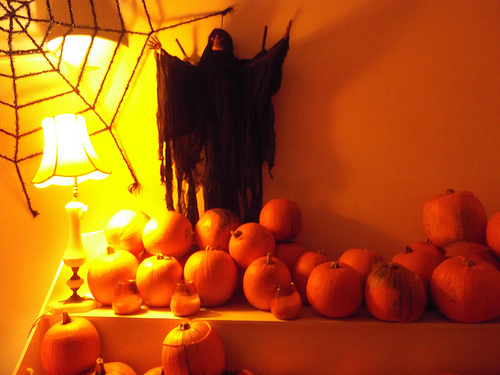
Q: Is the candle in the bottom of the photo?
A: Yes, the candle is in the bottom of the image.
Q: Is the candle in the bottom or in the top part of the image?
A: The candle is in the bottom of the image.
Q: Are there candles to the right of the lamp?
A: Yes, there is a candle to the right of the lamp.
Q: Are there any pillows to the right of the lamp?
A: No, there is a candle to the right of the lamp.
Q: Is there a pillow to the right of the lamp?
A: No, there is a candle to the right of the lamp.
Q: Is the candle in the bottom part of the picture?
A: Yes, the candle is in the bottom of the image.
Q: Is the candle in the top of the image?
A: No, the candle is in the bottom of the image.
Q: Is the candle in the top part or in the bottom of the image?
A: The candle is in the bottom of the image.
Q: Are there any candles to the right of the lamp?
A: Yes, there is a candle to the right of the lamp.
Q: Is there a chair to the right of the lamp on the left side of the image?
A: No, there is a candle to the right of the lamp.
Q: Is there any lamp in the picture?
A: Yes, there is a lamp.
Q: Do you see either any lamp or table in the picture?
A: Yes, there is a lamp.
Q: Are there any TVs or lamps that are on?
A: Yes, the lamp is on.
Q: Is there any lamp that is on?
A: Yes, there is a lamp that is on.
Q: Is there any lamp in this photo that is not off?
A: Yes, there is a lamp that is on.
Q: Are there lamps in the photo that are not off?
A: Yes, there is a lamp that is on.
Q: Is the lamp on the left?
A: Yes, the lamp is on the left of the image.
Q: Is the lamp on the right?
A: No, the lamp is on the left of the image.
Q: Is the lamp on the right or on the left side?
A: The lamp is on the left of the image.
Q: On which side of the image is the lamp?
A: The lamp is on the left of the image.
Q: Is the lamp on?
A: Yes, the lamp is on.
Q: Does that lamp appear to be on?
A: Yes, the lamp is on.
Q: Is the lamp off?
A: No, the lamp is on.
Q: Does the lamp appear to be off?
A: No, the lamp is on.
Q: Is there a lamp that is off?
A: No, there is a lamp but it is on.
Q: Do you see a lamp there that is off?
A: No, there is a lamp but it is on.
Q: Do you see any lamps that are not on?
A: No, there is a lamp but it is on.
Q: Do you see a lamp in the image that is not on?
A: No, there is a lamp but it is on.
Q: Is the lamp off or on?
A: The lamp is on.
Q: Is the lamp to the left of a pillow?
A: No, the lamp is to the left of a pumpkin.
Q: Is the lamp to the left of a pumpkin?
A: Yes, the lamp is to the left of a pumpkin.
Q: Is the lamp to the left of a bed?
A: No, the lamp is to the left of a pumpkin.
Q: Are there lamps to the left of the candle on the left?
A: Yes, there is a lamp to the left of the candle.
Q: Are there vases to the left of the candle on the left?
A: No, there is a lamp to the left of the candle.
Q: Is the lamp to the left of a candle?
A: Yes, the lamp is to the left of a candle.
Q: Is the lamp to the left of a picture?
A: No, the lamp is to the left of a candle.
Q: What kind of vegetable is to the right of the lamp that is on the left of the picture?
A: The vegetable is a pumpkin.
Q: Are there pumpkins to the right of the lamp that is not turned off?
A: Yes, there is a pumpkin to the right of the lamp.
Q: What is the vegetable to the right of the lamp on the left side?
A: The vegetable is a pumpkin.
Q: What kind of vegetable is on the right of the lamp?
A: The vegetable is a pumpkin.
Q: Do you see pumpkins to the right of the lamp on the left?
A: Yes, there is a pumpkin to the right of the lamp.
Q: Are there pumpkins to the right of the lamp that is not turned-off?
A: Yes, there is a pumpkin to the right of the lamp.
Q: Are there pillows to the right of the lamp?
A: No, there is a pumpkin to the right of the lamp.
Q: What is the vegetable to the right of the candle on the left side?
A: The vegetable is a pumpkin.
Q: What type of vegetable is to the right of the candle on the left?
A: The vegetable is a pumpkin.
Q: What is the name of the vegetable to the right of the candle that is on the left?
A: The vegetable is a pumpkin.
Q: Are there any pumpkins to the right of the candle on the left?
A: Yes, there is a pumpkin to the right of the candle.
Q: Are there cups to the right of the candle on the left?
A: No, there is a pumpkin to the right of the candle.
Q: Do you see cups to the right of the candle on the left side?
A: No, there is a pumpkin to the right of the candle.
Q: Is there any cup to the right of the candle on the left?
A: No, there is a pumpkin to the right of the candle.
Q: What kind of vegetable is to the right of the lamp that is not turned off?
A: The vegetable is a pumpkin.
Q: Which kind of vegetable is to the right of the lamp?
A: The vegetable is a pumpkin.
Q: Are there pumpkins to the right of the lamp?
A: Yes, there is a pumpkin to the right of the lamp.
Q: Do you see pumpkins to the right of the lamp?
A: Yes, there is a pumpkin to the right of the lamp.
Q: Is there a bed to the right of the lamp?
A: No, there is a pumpkin to the right of the lamp.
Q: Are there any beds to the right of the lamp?
A: No, there is a pumpkin to the right of the lamp.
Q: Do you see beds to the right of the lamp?
A: No, there is a pumpkin to the right of the lamp.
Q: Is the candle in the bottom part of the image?
A: Yes, the candle is in the bottom of the image.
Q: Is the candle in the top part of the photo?
A: No, the candle is in the bottom of the image.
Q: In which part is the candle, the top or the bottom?
A: The candle is in the bottom of the image.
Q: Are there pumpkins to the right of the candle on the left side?
A: Yes, there is a pumpkin to the right of the candle.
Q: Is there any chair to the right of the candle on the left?
A: No, there is a pumpkin to the right of the candle.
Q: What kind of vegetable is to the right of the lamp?
A: The vegetable is a pumpkin.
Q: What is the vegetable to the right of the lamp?
A: The vegetable is a pumpkin.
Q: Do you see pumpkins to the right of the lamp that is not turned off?
A: Yes, there is a pumpkin to the right of the lamp.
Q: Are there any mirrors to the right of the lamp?
A: No, there is a pumpkin to the right of the lamp.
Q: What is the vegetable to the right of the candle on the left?
A: The vegetable is a pumpkin.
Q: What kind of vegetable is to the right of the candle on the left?
A: The vegetable is a pumpkin.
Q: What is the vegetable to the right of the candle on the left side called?
A: The vegetable is a pumpkin.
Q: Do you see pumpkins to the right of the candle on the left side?
A: Yes, there is a pumpkin to the right of the candle.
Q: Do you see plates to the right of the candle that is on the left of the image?
A: No, there is a pumpkin to the right of the candle.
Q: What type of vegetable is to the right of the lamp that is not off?
A: The vegetable is a pumpkin.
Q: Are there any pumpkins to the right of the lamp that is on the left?
A: Yes, there is a pumpkin to the right of the lamp.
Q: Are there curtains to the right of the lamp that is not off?
A: No, there is a pumpkin to the right of the lamp.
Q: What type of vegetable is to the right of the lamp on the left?
A: The vegetable is a pumpkin.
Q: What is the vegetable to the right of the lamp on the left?
A: The vegetable is a pumpkin.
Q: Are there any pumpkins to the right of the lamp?
A: Yes, there is a pumpkin to the right of the lamp.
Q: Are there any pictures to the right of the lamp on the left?
A: No, there is a pumpkin to the right of the lamp.